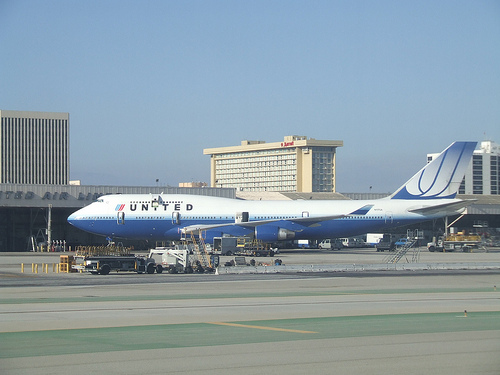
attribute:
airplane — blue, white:
[68, 142, 478, 247]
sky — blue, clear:
[1, 4, 498, 71]